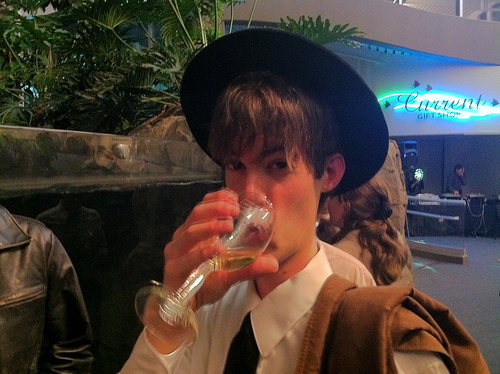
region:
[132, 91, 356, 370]
a person drinking from a glass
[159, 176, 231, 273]
the hand of a person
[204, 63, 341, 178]
a person with long bangs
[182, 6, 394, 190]
a person wearing a black hat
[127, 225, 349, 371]
a person wearing a white shirt and black tie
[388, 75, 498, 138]
a neon sign on the wall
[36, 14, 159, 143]
green plants in a planter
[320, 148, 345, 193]
the ear of a person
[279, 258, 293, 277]
a mole on the skin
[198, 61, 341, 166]
a person with brown hair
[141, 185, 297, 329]
Hand holding a glass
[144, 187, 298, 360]
Glass by a mouth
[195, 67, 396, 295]
Boy with brown hair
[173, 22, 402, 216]
Black hat on a head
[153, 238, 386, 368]
White shirt with black tie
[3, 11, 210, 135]
Green plants in a room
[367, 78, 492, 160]
Sign on a wall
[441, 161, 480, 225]
Man standing by a wall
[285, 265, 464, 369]
Brown jacket on a shoulder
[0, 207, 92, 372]
Brown jacket on a person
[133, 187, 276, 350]
a wine glass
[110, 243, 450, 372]
person wearing a white dress shirt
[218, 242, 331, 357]
collar on dress shirt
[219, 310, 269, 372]
person wearing a black neck tie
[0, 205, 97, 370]
a brown leather jacket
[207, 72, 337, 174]
brown hair over eyes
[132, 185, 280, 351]
wine glass in hand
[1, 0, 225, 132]
plants behind person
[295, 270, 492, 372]
brown jacket over shoulder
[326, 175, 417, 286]
woman with long brown hair behind person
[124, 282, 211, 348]
stem of clear glass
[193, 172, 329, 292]
woman drinking liquid from glass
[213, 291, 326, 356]
white collar around woman's neck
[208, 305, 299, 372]
immaculate tied black necktie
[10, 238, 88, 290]
wrinkles in long sleeve shirt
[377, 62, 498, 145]
bright light on wall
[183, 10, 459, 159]
black brimmed hat on woman's head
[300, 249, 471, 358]
brown clothing on woman's shoulders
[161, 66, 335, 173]
black bangs in woman's face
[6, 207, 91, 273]
collar of black leather jacket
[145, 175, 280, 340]
glass of wine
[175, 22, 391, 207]
dark colored Fedora hat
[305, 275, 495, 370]
light brown cape on shoulder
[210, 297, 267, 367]
dark colored necktie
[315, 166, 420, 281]
other people chatting in background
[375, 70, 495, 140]
gift shop behind the boy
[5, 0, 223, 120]
decorative foliage overhead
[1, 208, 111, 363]
dark brown leather jacket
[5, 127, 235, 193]
stone-like edifice for plants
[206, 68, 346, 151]
straight dark brown hair